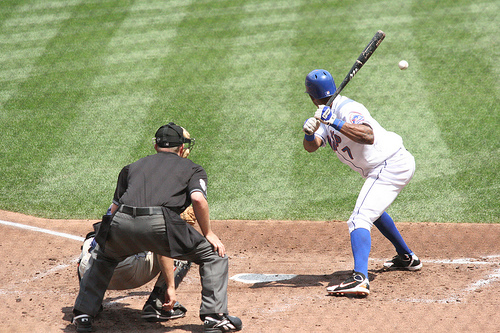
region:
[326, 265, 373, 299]
piece of baseball uniform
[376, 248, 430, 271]
piece of baseball uniform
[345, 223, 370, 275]
piece of baseball uniform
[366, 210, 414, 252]
piece of baseball uniform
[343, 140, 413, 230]
piece of baseball uniform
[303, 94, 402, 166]
piece of baseball uniform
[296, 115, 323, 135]
piece of baseball uniform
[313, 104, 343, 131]
piece of baseball uniform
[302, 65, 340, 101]
piece of baseball uniform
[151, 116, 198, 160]
piece of baseball uniform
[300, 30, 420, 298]
The hitter is about to hit a baseball.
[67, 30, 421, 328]
Catcher waiting to catch the ball.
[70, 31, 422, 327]
Umpire standing behind catcher and hitter.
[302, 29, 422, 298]
Baseball player swinging his bat.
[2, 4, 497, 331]
A baseball game.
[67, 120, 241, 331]
Umpire is crouching.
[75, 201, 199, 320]
Catcher is crouching.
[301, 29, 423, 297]
Hitter holding a baseball bat.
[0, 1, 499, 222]
Turf is green.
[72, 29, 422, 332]
Three people playing baseball.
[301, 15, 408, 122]
bat in the photo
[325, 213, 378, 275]
blue sock on batter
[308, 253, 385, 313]
shoes of the batter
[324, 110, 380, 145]
arm of the person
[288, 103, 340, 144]
gloves on the person's hands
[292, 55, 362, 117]
helmet on person's head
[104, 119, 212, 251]
umpire behind the plate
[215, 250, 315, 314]
plate on the ground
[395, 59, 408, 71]
a white baseball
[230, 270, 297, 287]
a white base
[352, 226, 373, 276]
a long blue sock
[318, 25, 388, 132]
a long black bat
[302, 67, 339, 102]
a blue helmet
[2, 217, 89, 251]
a long white line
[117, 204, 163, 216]
part of a man's black belt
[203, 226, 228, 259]
the hand of a man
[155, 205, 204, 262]
part of a black apron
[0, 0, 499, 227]
a section of green grass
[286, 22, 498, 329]
the man is at bat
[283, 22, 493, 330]
he plays for the New York Mets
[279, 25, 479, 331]
his uniform is white, blue, and orange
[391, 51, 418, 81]
this is a white baseball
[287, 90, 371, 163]
blue and white batting gloves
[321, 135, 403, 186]
he wears number 7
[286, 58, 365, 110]
a blue batting helmet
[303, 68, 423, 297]
batter wearing a blue helmet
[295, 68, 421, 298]
batter wearing long blue socks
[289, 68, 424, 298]
batter swinging a black bat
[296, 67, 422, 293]
batter wearing a white uniform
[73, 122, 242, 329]
umpire wearing a black hat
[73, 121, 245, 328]
umpire wearing black shoes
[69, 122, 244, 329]
umpire wearing a black shirt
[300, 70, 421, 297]
batter wearing white gloves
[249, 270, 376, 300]
shadow of batter reflected on the ground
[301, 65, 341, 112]
the helmet is blue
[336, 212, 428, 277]
the socks are blue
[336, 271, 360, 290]
a nike sign on shoe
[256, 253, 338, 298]
the man's shadow on ground